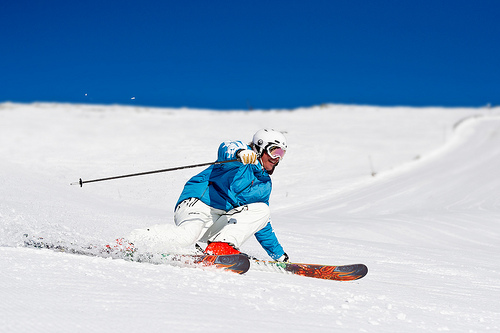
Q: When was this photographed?
A: Daytime.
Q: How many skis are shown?
A: Two.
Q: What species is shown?
A: Homo sapien.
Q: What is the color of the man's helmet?
A: White.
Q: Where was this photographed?
A: Mountain.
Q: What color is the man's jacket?
A: Blue.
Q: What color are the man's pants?
A: White.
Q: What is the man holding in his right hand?
A: Ski pole.